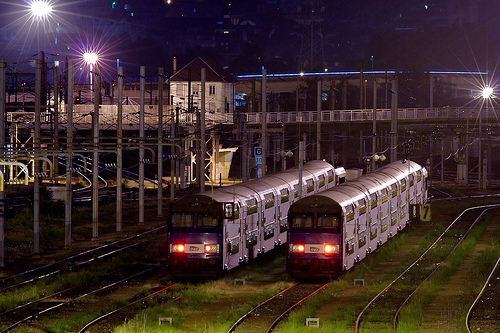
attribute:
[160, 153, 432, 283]
train cars — parked, at the station, parked together, empty, parked for repairs, for passengers, guarded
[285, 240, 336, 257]
lights — on, orange, bright, red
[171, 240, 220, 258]
lights — on, orange, bright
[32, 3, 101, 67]
lights — on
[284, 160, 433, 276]
train — front section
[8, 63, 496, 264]
fence — tall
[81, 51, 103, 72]
light — bright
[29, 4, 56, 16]
light — bright, white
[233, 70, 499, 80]
lights — blue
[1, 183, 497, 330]
train tracks — side by side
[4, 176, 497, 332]
ground — grassy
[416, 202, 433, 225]
sign — 7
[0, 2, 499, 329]
picture — nightime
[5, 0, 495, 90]
sky — dark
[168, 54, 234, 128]
building — white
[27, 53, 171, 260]
poles — tall, aligned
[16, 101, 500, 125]
walkway — raised